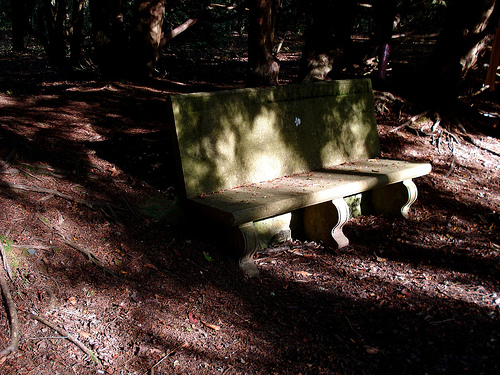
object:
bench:
[171, 75, 432, 278]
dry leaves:
[0, 251, 500, 373]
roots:
[400, 88, 499, 159]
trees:
[0, 1, 499, 77]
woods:
[0, 0, 499, 373]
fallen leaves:
[188, 146, 431, 225]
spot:
[293, 114, 304, 128]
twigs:
[149, 345, 178, 374]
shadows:
[0, 1, 499, 374]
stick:
[265, 242, 323, 262]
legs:
[306, 197, 348, 250]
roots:
[0, 258, 17, 363]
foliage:
[2, 42, 173, 195]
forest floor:
[375, 1, 499, 155]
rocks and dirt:
[379, 85, 499, 162]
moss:
[172, 76, 378, 196]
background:
[4, 0, 93, 78]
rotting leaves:
[1, 81, 176, 372]